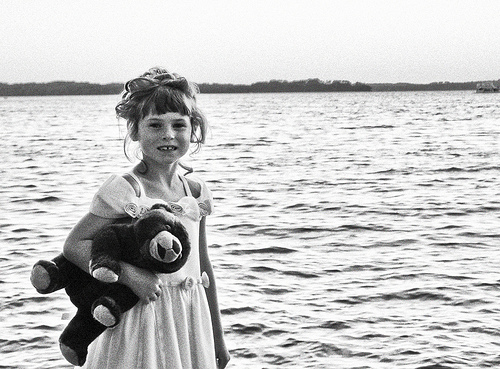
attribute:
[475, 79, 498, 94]
dock — in the background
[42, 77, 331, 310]
picture taken — during the day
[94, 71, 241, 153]
style — fancy 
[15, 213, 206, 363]
bear — white, nose 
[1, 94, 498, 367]
water — dark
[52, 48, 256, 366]
girl — little 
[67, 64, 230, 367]
girl — standing 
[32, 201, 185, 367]
bear — stuffed, neck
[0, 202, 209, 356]
teddy bear — teddy 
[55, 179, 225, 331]
teddy bear — large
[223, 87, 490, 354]
water — small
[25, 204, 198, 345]
bear — stuffed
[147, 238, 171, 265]
mouth — black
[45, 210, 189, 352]
bear — teddy 